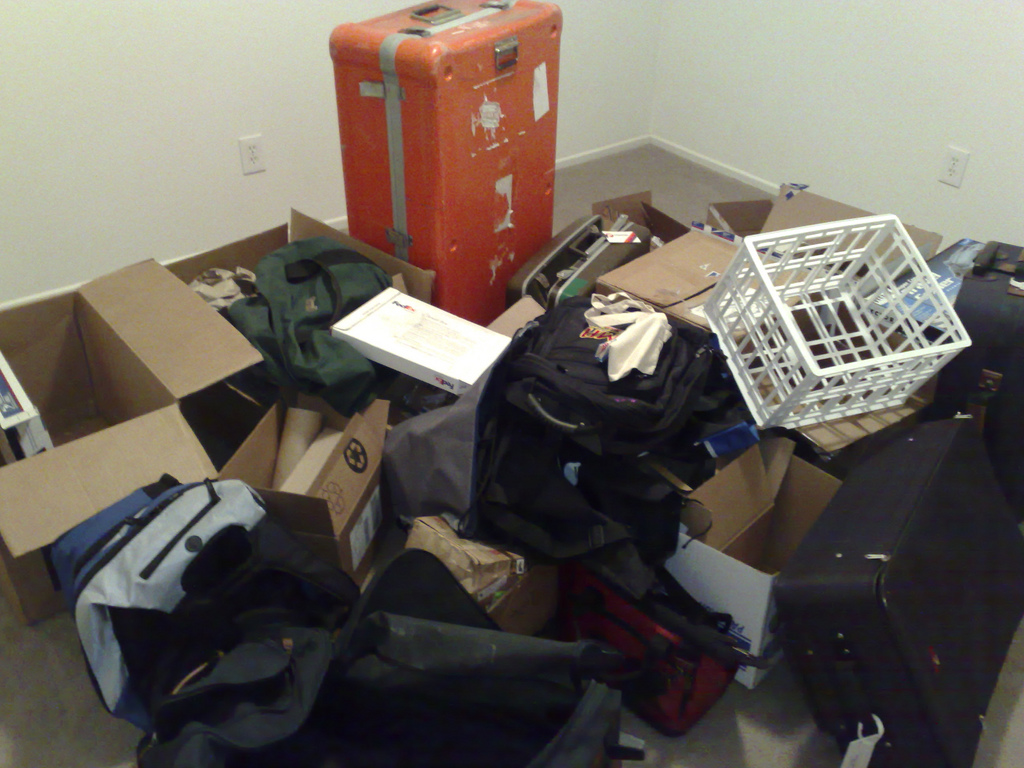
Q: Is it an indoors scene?
A: Yes, it is indoors.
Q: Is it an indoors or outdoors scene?
A: It is indoors.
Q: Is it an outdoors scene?
A: No, it is indoors.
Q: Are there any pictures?
A: No, there are no pictures.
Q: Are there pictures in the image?
A: No, there are no pictures.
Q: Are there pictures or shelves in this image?
A: No, there are no pictures or shelves.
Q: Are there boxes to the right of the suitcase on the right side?
A: No, the box is to the left of the suitcase.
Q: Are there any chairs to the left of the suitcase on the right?
A: No, there is a box to the left of the suitcase.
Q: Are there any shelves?
A: No, there are no shelves.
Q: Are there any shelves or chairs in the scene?
A: No, there are no shelves or chairs.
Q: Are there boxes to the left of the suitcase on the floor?
A: Yes, there are boxes to the left of the suitcase.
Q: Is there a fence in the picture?
A: No, there are no fences.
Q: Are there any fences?
A: No, there are no fences.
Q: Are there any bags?
A: Yes, there is a bag.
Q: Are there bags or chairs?
A: Yes, there is a bag.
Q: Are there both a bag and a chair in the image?
A: No, there is a bag but no chairs.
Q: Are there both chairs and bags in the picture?
A: No, there is a bag but no chairs.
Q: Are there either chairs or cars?
A: No, there are no chairs or cars.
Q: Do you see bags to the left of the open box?
A: Yes, there is a bag to the left of the box.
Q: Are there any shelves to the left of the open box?
A: No, there is a bag to the left of the box.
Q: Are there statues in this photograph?
A: No, there are no statues.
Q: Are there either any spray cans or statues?
A: No, there are no statues or spray cans.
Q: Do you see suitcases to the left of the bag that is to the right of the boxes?
A: No, the suitcase is to the right of the bag.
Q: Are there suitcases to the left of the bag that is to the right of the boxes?
A: No, the suitcase is to the right of the bag.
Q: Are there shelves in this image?
A: No, there are no shelves.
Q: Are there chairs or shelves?
A: No, there are no shelves or chairs.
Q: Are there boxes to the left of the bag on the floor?
A: Yes, there is a box to the left of the bag.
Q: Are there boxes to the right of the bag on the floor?
A: No, the box is to the left of the bag.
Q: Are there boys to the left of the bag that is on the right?
A: No, there is a box to the left of the bag.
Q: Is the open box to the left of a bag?
A: Yes, the box is to the left of a bag.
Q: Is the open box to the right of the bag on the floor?
A: No, the box is to the left of the bag.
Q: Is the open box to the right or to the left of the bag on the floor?
A: The box is to the left of the bag.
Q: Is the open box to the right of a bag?
A: Yes, the box is to the right of a bag.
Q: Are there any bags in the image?
A: Yes, there is a bag.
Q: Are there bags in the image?
A: Yes, there is a bag.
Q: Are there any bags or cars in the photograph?
A: Yes, there is a bag.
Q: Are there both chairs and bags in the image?
A: No, there is a bag but no chairs.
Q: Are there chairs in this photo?
A: No, there are no chairs.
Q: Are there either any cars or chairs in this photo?
A: No, there are no chairs or cars.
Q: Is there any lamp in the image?
A: No, there are no lamps.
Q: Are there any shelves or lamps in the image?
A: No, there are no lamps or shelves.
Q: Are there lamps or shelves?
A: No, there are no lamps or shelves.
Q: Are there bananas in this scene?
A: No, there are no bananas.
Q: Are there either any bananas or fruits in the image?
A: No, there are no bananas or fruits.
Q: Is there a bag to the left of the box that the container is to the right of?
A: Yes, there are bags to the left of the box.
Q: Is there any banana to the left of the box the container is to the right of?
A: No, there are bags to the left of the box.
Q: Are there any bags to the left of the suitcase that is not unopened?
A: Yes, there are bags to the left of the suitcase.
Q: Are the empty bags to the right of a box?
A: Yes, the bags are to the right of a box.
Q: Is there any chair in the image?
A: No, there are no chairs.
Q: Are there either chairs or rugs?
A: No, there are no chairs or rugs.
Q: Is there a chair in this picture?
A: No, there are no chairs.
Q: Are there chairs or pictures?
A: No, there are no chairs or pictures.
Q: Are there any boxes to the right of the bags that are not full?
A: Yes, there is a box to the right of the bags.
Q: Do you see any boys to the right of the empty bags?
A: No, there is a box to the right of the bags.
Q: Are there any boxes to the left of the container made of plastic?
A: Yes, there is a box to the left of the container.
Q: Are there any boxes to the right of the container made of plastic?
A: No, the box is to the left of the container.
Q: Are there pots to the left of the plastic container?
A: No, there is a box to the left of the container.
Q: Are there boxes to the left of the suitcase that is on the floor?
A: Yes, there is a box to the left of the suitcase.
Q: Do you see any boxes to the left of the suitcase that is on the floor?
A: Yes, there is a box to the left of the suitcase.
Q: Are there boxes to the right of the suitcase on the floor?
A: No, the box is to the left of the suitcase.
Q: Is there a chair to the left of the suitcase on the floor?
A: No, there is a box to the left of the suitcase.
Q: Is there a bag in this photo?
A: Yes, there is a bag.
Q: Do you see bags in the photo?
A: Yes, there is a bag.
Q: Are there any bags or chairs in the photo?
A: Yes, there is a bag.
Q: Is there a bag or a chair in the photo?
A: Yes, there is a bag.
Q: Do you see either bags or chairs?
A: Yes, there is a bag.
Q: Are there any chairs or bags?
A: Yes, there is a bag.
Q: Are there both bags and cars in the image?
A: No, there is a bag but no cars.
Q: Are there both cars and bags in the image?
A: No, there is a bag but no cars.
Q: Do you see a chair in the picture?
A: No, there are no chairs.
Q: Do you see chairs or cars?
A: No, there are no chairs or cars.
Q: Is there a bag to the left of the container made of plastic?
A: Yes, there is a bag to the left of the container.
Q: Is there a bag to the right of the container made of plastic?
A: No, the bag is to the left of the container.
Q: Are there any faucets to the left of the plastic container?
A: No, there is a bag to the left of the container.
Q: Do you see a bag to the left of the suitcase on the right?
A: Yes, there is a bag to the left of the suitcase.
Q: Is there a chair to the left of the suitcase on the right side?
A: No, there is a bag to the left of the suitcase.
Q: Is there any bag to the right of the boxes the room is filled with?
A: Yes, there is a bag to the right of the boxes.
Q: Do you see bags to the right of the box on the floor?
A: Yes, there is a bag to the right of the box.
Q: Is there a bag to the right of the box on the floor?
A: Yes, there is a bag to the right of the box.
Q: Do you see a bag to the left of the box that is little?
A: No, the bag is to the right of the box.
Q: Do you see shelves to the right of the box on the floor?
A: No, there is a bag to the right of the box.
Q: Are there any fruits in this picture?
A: No, there are no fruits.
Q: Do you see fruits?
A: No, there are no fruits.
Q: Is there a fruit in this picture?
A: No, there are no fruits.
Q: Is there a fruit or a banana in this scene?
A: No, there are no fruits or bananas.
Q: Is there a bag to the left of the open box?
A: Yes, there are bags to the left of the box.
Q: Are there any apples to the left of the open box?
A: No, there are bags to the left of the box.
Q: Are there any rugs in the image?
A: No, there are no rugs.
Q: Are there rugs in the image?
A: No, there are no rugs.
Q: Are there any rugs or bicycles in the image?
A: No, there are no rugs or bicycles.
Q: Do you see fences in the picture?
A: No, there are no fences.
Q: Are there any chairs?
A: No, there are no chairs.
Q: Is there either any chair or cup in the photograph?
A: No, there are no chairs or cups.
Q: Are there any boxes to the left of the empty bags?
A: Yes, there is a box to the left of the bags.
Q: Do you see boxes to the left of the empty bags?
A: Yes, there is a box to the left of the bags.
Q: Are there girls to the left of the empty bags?
A: No, there is a box to the left of the bags.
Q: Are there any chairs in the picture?
A: No, there are no chairs.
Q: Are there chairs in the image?
A: No, there are no chairs.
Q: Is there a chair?
A: No, there are no chairs.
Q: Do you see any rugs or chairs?
A: No, there are no chairs or rugs.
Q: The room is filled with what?
A: The room is filled with boxes.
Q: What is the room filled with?
A: The room is filled with boxes.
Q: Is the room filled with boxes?
A: Yes, the room is filled with boxes.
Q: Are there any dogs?
A: No, there are no dogs.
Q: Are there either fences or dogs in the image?
A: No, there are no dogs or fences.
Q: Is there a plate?
A: No, there are no plates.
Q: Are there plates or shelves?
A: No, there are no plates or shelves.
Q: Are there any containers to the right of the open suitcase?
A: Yes, there is a container to the right of the suitcase.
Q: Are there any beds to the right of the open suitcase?
A: No, there is a container to the right of the suitcase.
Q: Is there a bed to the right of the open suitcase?
A: No, there is a container to the right of the suitcase.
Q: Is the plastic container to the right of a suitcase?
A: Yes, the container is to the right of a suitcase.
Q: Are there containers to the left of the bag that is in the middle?
A: No, the container is to the right of the bag.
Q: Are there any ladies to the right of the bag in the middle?
A: No, there is a container to the right of the bag.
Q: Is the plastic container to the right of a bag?
A: Yes, the container is to the right of a bag.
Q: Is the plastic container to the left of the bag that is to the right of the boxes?
A: No, the container is to the right of the bag.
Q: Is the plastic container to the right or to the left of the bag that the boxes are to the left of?
A: The container is to the right of the bag.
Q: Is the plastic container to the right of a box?
A: Yes, the container is to the right of a box.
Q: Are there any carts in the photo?
A: No, there are no carts.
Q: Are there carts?
A: No, there are no carts.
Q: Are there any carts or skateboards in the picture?
A: No, there are no carts or skateboards.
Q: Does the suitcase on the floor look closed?
A: No, the suitcase is open.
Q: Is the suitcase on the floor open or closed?
A: The suitcase is open.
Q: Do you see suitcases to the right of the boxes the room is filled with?
A: Yes, there is a suitcase to the right of the boxes.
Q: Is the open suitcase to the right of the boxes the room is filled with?
A: Yes, the suitcase is to the right of the boxes.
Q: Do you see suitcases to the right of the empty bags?
A: Yes, there is a suitcase to the right of the bags.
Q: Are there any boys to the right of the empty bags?
A: No, there is a suitcase to the right of the bags.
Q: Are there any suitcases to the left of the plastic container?
A: Yes, there is a suitcase to the left of the container.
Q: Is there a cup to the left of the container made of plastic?
A: No, there is a suitcase to the left of the container.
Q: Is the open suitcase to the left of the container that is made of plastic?
A: Yes, the suitcase is to the left of the container.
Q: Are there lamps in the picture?
A: No, there are no lamps.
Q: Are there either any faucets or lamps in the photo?
A: No, there are no lamps or faucets.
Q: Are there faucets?
A: No, there are no faucets.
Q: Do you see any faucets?
A: No, there are no faucets.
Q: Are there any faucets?
A: No, there are no faucets.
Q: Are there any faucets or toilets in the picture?
A: No, there are no faucets or toilets.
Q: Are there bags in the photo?
A: Yes, there is a bag.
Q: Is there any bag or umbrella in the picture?
A: Yes, there is a bag.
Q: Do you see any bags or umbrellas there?
A: Yes, there is a bag.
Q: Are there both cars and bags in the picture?
A: No, there is a bag but no cars.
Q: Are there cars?
A: No, there are no cars.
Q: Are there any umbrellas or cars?
A: No, there are no cars or umbrellas.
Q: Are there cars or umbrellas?
A: No, there are no cars or umbrellas.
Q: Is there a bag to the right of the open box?
A: Yes, there is a bag to the right of the box.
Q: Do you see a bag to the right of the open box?
A: Yes, there is a bag to the right of the box.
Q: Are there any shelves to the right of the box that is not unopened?
A: No, there is a bag to the right of the box.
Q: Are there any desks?
A: No, there are no desks.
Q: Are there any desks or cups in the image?
A: No, there are no desks or cups.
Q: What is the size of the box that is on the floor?
A: The box is small.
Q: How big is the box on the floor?
A: The box is small.